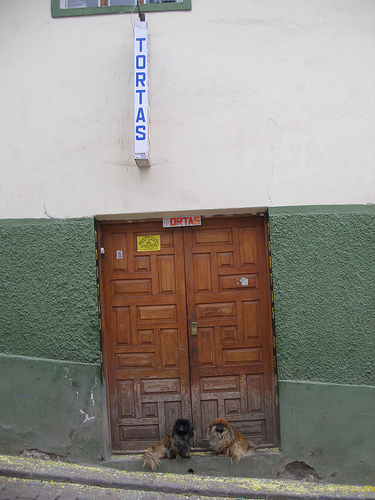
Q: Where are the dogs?
A: In front of the doors.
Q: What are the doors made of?
A: Wood.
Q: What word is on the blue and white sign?
A: Tortas.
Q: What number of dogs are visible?
A: 3.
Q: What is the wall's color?
A: Green and white.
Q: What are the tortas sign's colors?
A: Blue and white.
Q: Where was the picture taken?
A: Outside a buildign.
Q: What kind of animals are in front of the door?
A: Dogs.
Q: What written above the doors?
A: "ORTAS".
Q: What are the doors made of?
A: Wood.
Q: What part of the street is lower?
A: The right.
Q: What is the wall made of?
A: Cement.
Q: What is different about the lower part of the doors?
A: The finish is worn off.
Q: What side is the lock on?
A: The right.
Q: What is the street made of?
A: Bricks.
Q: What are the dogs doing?
A: Sitting.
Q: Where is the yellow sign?
A: On the left side of the door.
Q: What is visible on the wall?
A: A sign.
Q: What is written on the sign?
A: Tortas.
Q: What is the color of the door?
A: Brown.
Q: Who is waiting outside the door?
A: Dogs.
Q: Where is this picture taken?
A: Outside the building.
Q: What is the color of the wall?
A: Green and white.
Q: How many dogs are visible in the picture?
A: Three.